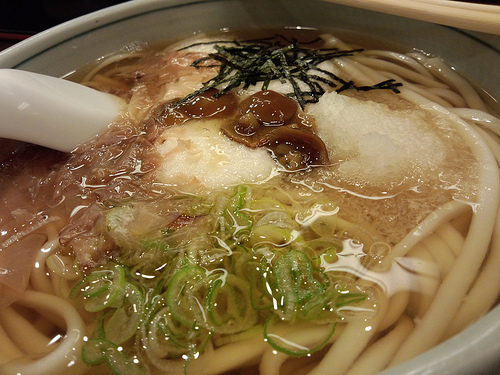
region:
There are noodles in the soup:
[330, 205, 495, 350]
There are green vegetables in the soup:
[58, 206, 338, 343]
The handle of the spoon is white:
[1, 58, 148, 169]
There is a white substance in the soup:
[135, 48, 447, 218]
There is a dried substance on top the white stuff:
[186, 32, 341, 111]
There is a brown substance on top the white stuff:
[171, 84, 333, 191]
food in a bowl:
[21, 40, 459, 359]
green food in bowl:
[104, 213, 308, 346]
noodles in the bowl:
[333, 182, 484, 307]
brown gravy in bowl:
[188, 60, 332, 191]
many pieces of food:
[87, 113, 429, 322]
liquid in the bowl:
[301, 177, 428, 280]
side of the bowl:
[388, 320, 497, 372]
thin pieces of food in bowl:
[222, 26, 339, 93]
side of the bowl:
[43, 8, 120, 64]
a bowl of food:
[24, 13, 493, 373]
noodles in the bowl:
[342, 103, 498, 324]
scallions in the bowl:
[87, 198, 343, 364]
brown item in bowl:
[170, 50, 330, 190]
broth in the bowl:
[85, 183, 419, 371]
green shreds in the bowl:
[187, 18, 391, 118]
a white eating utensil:
[9, 37, 156, 174]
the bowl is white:
[19, 8, 497, 370]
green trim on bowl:
[16, 2, 498, 372]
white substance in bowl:
[294, 58, 466, 208]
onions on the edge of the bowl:
[369, 182, 494, 373]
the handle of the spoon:
[0, 70, 120, 152]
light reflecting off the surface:
[319, 239, 427, 291]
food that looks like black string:
[184, 35, 399, 105]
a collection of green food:
[90, 187, 344, 368]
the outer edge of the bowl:
[0, 0, 140, 73]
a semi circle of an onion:
[7, 286, 82, 373]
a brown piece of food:
[220, 91, 324, 170]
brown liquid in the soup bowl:
[62, 41, 162, 103]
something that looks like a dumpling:
[147, 125, 267, 195]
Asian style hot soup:
[0, 20, 496, 372]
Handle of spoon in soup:
[1, 63, 128, 163]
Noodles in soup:
[5, 36, 498, 369]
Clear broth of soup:
[5, 17, 495, 369]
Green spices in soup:
[175, 30, 403, 110]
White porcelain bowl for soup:
[2, 3, 499, 373]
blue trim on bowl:
[5, 6, 499, 70]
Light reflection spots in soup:
[1, 21, 494, 368]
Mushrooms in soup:
[158, 86, 334, 170]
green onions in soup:
[72, 185, 364, 368]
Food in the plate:
[5, 107, 465, 331]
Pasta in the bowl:
[421, 254, 498, 323]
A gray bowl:
[437, 332, 491, 373]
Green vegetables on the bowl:
[112, 265, 326, 341]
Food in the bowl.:
[115, 120, 472, 342]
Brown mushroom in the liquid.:
[213, 79, 318, 161]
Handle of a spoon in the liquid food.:
[13, 70, 134, 150]